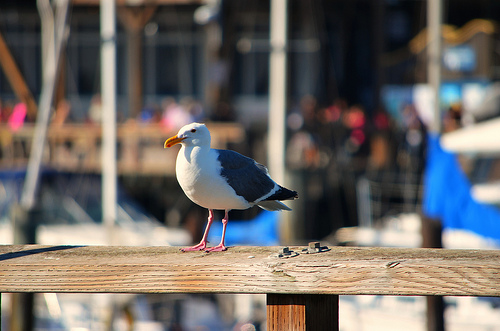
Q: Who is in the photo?
A: Noone.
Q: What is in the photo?
A: A bird.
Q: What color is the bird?
A: White.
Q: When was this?
A: Daytime.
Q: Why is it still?
A: To rest.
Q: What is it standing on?
A: Legs.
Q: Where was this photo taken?
A: On a wooden rail.